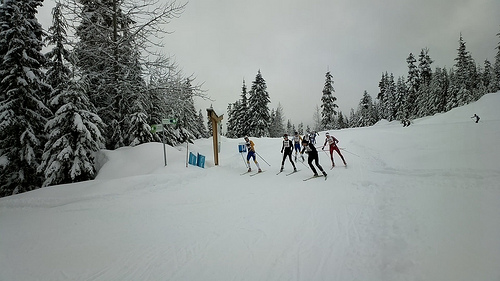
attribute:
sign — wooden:
[215, 119, 221, 151]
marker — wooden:
[203, 103, 228, 167]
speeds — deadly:
[210, 119, 408, 186]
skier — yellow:
[243, 135, 262, 172]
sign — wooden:
[205, 105, 225, 166]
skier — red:
[317, 127, 352, 171]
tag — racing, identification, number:
[266, 146, 326, 166]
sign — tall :
[205, 100, 230, 169]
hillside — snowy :
[126, 100, 497, 278]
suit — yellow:
[243, 139, 259, 168]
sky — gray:
[172, 20, 392, 81]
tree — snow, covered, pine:
[245, 68, 272, 144]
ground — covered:
[202, 116, 356, 186]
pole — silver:
[160, 113, 172, 163]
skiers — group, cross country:
[228, 124, 354, 192]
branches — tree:
[68, 137, 95, 178]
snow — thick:
[50, 85, 498, 267]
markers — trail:
[186, 88, 227, 217]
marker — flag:
[188, 95, 253, 151]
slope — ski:
[250, 139, 375, 277]